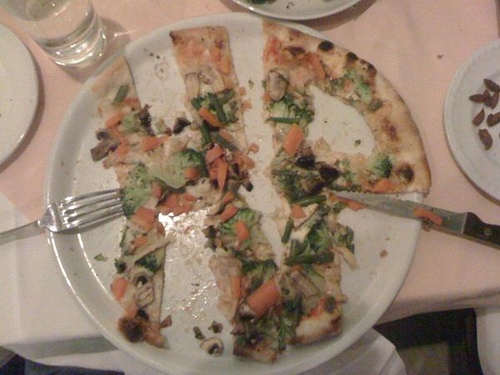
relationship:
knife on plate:
[336, 187, 500, 249] [41, 10, 437, 374]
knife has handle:
[336, 187, 500, 249] [461, 209, 499, 250]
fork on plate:
[0, 188, 128, 251] [41, 10, 437, 374]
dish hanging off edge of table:
[92, 18, 431, 364] [1, 291, 464, 375]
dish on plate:
[92, 18, 431, 364] [41, 10, 437, 374]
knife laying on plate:
[336, 187, 500, 249] [41, 10, 437, 374]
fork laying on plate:
[0, 188, 128, 251] [41, 10, 437, 374]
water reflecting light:
[15, 4, 111, 72] [52, 33, 107, 69]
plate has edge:
[41, 10, 437, 374] [116, 321, 394, 374]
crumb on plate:
[201, 338, 227, 359] [41, 10, 437, 374]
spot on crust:
[318, 38, 336, 53] [261, 21, 393, 94]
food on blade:
[410, 206, 447, 228] [331, 188, 467, 241]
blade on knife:
[331, 188, 467, 241] [336, 187, 500, 249]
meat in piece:
[240, 319, 271, 352] [231, 316, 285, 364]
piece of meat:
[231, 316, 285, 364] [240, 319, 271, 352]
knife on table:
[336, 187, 500, 249] [338, 13, 499, 294]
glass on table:
[3, 1, 113, 73] [338, 13, 499, 294]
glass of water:
[3, 1, 113, 73] [15, 4, 111, 72]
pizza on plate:
[92, 18, 431, 364] [41, 10, 437, 374]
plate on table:
[41, 10, 437, 374] [338, 13, 499, 294]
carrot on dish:
[249, 281, 283, 312] [92, 18, 431, 364]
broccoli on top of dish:
[278, 158, 341, 200] [92, 18, 431, 364]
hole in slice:
[301, 83, 378, 160] [255, 22, 431, 205]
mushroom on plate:
[201, 338, 227, 359] [41, 10, 437, 374]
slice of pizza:
[255, 22, 431, 205] [92, 18, 431, 364]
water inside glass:
[15, 4, 111, 72] [3, 1, 113, 73]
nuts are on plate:
[471, 69, 499, 154] [443, 36, 499, 200]